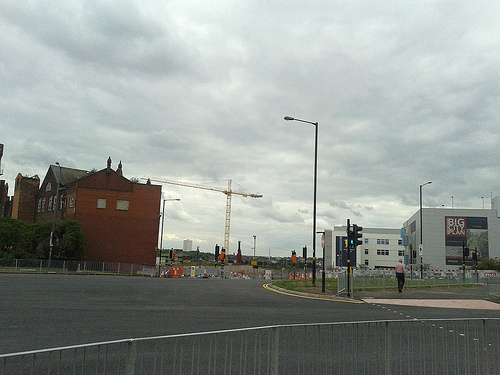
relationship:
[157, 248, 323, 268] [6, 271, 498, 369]
construction site at sidewalk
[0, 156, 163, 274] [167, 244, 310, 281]
building next to construction site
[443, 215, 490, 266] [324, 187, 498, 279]
advertisement on side of building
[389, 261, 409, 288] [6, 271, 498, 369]
man walking on sidewalk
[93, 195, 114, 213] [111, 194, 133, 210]
blinds are on window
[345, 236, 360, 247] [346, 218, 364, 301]
light on traffic light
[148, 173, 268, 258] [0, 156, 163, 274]
construction crane behind building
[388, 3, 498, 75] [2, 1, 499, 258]
clouds in sky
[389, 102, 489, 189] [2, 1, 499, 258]
clouds in sky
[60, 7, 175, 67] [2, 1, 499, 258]
clouds in sky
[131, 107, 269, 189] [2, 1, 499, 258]
clouds in sky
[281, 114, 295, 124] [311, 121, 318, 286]
light on light pole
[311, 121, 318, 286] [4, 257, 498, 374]
light pole on street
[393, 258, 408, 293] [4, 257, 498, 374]
man walking in street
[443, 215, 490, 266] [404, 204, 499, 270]
advertisement on building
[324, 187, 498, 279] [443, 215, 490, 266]
building have advertisement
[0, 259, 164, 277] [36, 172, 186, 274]
fence in front of building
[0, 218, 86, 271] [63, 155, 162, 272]
bushes are in front of building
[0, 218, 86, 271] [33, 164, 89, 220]
bushes are in front of building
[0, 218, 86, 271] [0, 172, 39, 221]
bushes are in front of building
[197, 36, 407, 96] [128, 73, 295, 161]
clouds are in sky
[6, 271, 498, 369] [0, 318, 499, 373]
sidewalk has railing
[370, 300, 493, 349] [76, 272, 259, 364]
line are in street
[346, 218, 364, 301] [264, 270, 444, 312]
traffic light on street corner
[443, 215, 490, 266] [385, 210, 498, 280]
advertisement on building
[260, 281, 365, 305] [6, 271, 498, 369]
line on sidewalk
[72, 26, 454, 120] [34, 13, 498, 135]
sky has grey clouds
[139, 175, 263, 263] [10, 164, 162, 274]
construction crane for building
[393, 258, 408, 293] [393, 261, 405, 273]
man wears shirt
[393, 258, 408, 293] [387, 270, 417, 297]
man wears chinos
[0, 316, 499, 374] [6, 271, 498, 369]
fence blocking sidewalk